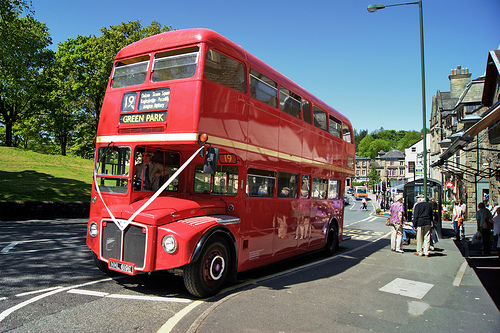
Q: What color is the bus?
A: Red.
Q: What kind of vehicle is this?
A: A bus.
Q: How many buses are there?
A: There is one.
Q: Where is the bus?
A: On the road.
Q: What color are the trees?
A: Green.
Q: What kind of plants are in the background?
A: Trees.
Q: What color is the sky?
A: Blue.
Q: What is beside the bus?
A: Buildings.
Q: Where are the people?
A: On the sidewalk.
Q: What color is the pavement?
A: Black.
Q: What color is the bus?
A: Red.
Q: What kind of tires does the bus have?
A: Large.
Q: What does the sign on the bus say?
A: Green Park.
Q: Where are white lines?
A: On the road.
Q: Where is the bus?
A: In the street.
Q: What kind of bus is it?
A: A double decker bus.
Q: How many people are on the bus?
A: 0.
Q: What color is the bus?
A: Red and yellow.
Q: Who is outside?
A: The waiting passengers.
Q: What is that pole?
A: A street lamp.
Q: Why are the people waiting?
A: For the bus.